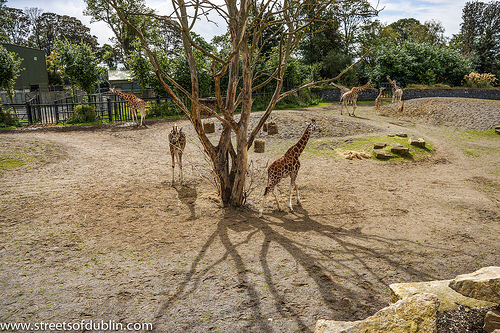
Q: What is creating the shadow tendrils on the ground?
A: The tree in the middle of the enclosure.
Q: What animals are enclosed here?
A: Giraffes.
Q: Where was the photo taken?
A: Zoo.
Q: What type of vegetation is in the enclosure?
A: Grass.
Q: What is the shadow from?
A: Tree.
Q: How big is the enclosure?
A: 200 feet.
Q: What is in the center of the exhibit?
A: Tree.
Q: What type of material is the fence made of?
A: Iron.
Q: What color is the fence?
A: Black.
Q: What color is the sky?
A: Blue.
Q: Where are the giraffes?
A: At the zoo.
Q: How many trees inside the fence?
A: One.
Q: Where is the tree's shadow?
A: On the ground.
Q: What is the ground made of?
A: Soil.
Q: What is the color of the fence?
A: Black.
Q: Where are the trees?
A: Behind the fence.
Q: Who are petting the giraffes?
A: No one.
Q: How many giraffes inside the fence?
A: Eight.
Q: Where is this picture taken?
A: The zoo.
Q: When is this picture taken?
A: Daytime.